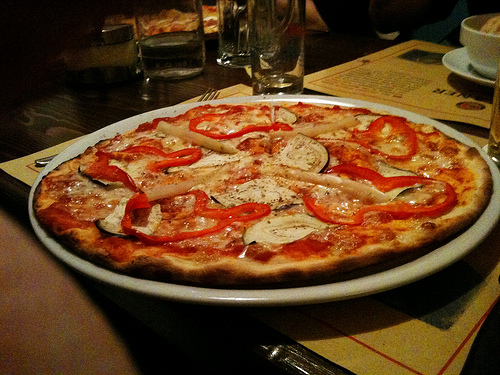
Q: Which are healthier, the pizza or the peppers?
A: The peppers are healthier than the pizza.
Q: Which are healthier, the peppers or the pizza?
A: The peppers are healthier than the pizza.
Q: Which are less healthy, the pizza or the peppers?
A: The pizza are less healthy than the peppers.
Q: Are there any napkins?
A: No, there are no napkins.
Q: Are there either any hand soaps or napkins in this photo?
A: No, there are no napkins or hand soaps.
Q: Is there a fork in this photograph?
A: Yes, there is a fork.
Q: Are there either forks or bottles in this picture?
A: Yes, there is a fork.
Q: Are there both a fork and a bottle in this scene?
A: No, there is a fork but no bottles.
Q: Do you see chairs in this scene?
A: No, there are no chairs.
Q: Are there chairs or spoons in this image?
A: No, there are no chairs or spoons.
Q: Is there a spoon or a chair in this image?
A: No, there are no chairs or spoons.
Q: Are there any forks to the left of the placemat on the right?
A: Yes, there is a fork to the left of the placemat.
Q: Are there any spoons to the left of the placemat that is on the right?
A: No, there is a fork to the left of the placemat.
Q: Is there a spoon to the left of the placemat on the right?
A: No, there is a fork to the left of the placemat.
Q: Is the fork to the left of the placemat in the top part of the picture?
A: Yes, the fork is to the left of the placemat.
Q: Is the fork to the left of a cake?
A: No, the fork is to the left of the placemat.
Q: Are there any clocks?
A: No, there are no clocks.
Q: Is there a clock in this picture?
A: No, there are no clocks.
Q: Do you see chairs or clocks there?
A: No, there are no clocks or chairs.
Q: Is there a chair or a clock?
A: No, there are no clocks or chairs.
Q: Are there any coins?
A: No, there are no coins.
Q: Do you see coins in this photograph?
A: No, there are no coins.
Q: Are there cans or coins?
A: No, there are no coins or cans.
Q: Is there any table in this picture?
A: Yes, there is a table.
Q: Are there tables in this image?
A: Yes, there is a table.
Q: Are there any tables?
A: Yes, there is a table.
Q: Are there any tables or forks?
A: Yes, there is a table.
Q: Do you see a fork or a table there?
A: Yes, there is a table.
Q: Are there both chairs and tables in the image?
A: No, there is a table but no chairs.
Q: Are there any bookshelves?
A: No, there are no bookshelves.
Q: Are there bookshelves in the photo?
A: No, there are no bookshelves.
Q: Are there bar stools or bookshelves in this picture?
A: No, there are no bookshelves or bar stools.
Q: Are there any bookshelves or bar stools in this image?
A: No, there are no bookshelves or bar stools.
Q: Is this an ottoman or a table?
A: This is a table.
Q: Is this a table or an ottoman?
A: This is a table.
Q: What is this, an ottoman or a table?
A: This is a table.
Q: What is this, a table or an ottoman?
A: This is a table.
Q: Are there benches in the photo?
A: No, there are no benches.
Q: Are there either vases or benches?
A: No, there are no benches or vases.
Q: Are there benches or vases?
A: No, there are no benches or vases.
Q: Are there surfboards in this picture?
A: No, there are no surfboards.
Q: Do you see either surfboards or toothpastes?
A: No, there are no surfboards or toothpastes.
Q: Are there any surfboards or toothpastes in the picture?
A: No, there are no surfboards or toothpastes.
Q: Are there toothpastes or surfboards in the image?
A: No, there are no surfboards or toothpastes.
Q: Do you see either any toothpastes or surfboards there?
A: No, there are no surfboards or toothpastes.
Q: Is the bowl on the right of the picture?
A: Yes, the bowl is on the right of the image.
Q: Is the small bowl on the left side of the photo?
A: No, the bowl is on the right of the image.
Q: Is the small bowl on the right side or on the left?
A: The bowl is on the right of the image.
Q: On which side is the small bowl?
A: The bowl is on the right of the image.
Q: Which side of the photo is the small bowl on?
A: The bowl is on the right of the image.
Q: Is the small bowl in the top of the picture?
A: Yes, the bowl is in the top of the image.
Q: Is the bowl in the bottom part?
A: No, the bowl is in the top of the image.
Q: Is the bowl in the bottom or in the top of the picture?
A: The bowl is in the top of the image.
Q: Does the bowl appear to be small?
A: Yes, the bowl is small.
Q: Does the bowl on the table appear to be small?
A: Yes, the bowl is small.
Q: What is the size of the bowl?
A: The bowl is small.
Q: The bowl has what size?
A: The bowl is small.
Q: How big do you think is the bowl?
A: The bowl is small.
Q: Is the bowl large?
A: No, the bowl is small.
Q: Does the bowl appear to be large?
A: No, the bowl is small.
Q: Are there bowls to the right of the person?
A: Yes, there is a bowl to the right of the person.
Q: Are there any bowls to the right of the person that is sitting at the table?
A: Yes, there is a bowl to the right of the person.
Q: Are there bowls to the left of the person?
A: No, the bowl is to the right of the person.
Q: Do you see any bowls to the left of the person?
A: No, the bowl is to the right of the person.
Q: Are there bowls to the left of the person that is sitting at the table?
A: No, the bowl is to the right of the person.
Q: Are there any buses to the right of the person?
A: No, there is a bowl to the right of the person.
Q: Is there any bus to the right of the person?
A: No, there is a bowl to the right of the person.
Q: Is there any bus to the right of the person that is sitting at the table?
A: No, there is a bowl to the right of the person.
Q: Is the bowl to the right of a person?
A: Yes, the bowl is to the right of a person.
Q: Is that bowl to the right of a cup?
A: No, the bowl is to the right of a person.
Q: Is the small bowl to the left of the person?
A: No, the bowl is to the right of the person.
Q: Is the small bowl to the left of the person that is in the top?
A: No, the bowl is to the right of the person.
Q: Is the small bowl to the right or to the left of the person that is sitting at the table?
A: The bowl is to the right of the person.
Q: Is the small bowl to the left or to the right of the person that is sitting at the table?
A: The bowl is to the right of the person.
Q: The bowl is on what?
A: The bowl is on the table.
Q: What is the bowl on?
A: The bowl is on the table.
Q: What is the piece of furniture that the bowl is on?
A: The piece of furniture is a table.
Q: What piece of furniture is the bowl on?
A: The bowl is on the table.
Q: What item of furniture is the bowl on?
A: The bowl is on the table.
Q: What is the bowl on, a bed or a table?
A: The bowl is on a table.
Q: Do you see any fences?
A: No, there are no fences.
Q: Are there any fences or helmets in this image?
A: No, there are no fences or helmets.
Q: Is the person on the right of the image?
A: Yes, the person is on the right of the image.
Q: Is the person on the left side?
A: No, the person is on the right of the image.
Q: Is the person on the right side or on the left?
A: The person is on the right of the image.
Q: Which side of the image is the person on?
A: The person is on the right of the image.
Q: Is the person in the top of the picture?
A: Yes, the person is in the top of the image.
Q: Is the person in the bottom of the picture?
A: No, the person is in the top of the image.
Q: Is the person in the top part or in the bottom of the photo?
A: The person is in the top of the image.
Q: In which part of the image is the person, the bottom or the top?
A: The person is in the top of the image.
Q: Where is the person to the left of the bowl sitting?
A: The person is sitting at the table.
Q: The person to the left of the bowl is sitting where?
A: The person is sitting at the table.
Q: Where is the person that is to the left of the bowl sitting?
A: The person is sitting at the table.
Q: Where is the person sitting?
A: The person is sitting at the table.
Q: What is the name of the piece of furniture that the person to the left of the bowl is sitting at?
A: The piece of furniture is a table.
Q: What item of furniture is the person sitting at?
A: The person is sitting at the table.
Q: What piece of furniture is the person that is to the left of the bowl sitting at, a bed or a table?
A: The person is sitting at a table.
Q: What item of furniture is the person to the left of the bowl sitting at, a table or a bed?
A: The person is sitting at a table.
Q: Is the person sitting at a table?
A: Yes, the person is sitting at a table.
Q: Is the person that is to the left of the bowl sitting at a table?
A: Yes, the person is sitting at a table.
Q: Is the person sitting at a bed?
A: No, the person is sitting at a table.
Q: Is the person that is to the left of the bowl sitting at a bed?
A: No, the person is sitting at a table.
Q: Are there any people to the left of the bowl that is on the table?
A: Yes, there is a person to the left of the bowl.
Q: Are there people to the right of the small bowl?
A: No, the person is to the left of the bowl.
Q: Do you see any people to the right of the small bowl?
A: No, the person is to the left of the bowl.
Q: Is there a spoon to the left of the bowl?
A: No, there is a person to the left of the bowl.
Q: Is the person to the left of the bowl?
A: Yes, the person is to the left of the bowl.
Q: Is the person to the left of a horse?
A: No, the person is to the left of the bowl.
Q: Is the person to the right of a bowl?
A: No, the person is to the left of a bowl.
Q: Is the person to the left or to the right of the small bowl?
A: The person is to the left of the bowl.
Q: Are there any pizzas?
A: Yes, there is a pizza.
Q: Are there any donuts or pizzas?
A: Yes, there is a pizza.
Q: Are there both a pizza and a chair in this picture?
A: No, there is a pizza but no chairs.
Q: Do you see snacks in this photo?
A: No, there are no snacks.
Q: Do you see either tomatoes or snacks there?
A: No, there are no snacks or tomatoes.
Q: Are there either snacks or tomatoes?
A: No, there are no snacks or tomatoes.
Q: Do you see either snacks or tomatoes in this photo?
A: No, there are no snacks or tomatoes.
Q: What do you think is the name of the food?
A: The food is a pizza.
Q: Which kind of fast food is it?
A: The food is a pizza.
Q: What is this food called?
A: This is a pizza.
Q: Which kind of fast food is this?
A: This is a pizza.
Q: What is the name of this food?
A: This is a pizza.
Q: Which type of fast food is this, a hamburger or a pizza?
A: This is a pizza.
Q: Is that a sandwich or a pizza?
A: That is a pizza.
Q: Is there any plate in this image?
A: Yes, there is a plate.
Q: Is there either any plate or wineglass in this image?
A: Yes, there is a plate.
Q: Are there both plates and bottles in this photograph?
A: No, there is a plate but no bottles.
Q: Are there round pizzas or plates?
A: Yes, there is a round plate.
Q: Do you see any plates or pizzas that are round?
A: Yes, the plate is round.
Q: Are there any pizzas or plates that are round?
A: Yes, the plate is round.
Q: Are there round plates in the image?
A: Yes, there is a round plate.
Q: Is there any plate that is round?
A: Yes, there is a plate that is round.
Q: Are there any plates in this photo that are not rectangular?
A: Yes, there is a round plate.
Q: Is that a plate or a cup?
A: That is a plate.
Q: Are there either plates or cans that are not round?
A: No, there is a plate but it is round.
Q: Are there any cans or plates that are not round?
A: No, there is a plate but it is round.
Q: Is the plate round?
A: Yes, the plate is round.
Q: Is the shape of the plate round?
A: Yes, the plate is round.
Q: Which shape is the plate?
A: The plate is round.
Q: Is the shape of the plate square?
A: No, the plate is round.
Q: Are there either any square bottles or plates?
A: No, there is a plate but it is round.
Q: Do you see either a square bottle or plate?
A: No, there is a plate but it is round.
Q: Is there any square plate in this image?
A: No, there is a plate but it is round.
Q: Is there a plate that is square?
A: No, there is a plate but it is round.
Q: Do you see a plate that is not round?
A: No, there is a plate but it is round.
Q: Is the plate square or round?
A: The plate is round.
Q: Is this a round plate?
A: Yes, this is a round plate.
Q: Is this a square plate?
A: No, this is a round plate.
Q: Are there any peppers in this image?
A: Yes, there are peppers.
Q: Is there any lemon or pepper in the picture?
A: Yes, there are peppers.